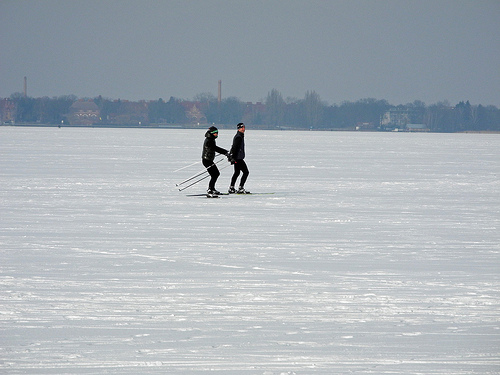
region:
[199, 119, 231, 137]
head of a person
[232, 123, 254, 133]
head of a person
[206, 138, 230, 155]
an arm of a person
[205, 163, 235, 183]
leg of a person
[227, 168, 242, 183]
leg of a person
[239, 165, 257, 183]
leg of a person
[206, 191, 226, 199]
feet of a person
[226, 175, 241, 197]
feet of a person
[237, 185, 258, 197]
feet of a person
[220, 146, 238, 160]
a hand of a person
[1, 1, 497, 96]
overcast sky on horizon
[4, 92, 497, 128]
hazy trees and buildings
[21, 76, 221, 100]
two smokestacks on horizon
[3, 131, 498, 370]
snow covered flat surface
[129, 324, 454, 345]
foot prints on snow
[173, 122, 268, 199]
two people on skis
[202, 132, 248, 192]
black clothing on bodies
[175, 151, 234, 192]
two sets of ski poles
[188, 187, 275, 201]
boots on top of skis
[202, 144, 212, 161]
light reflection on coat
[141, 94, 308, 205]
two people cross country skiing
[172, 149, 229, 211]
four ski poles on hands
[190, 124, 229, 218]
girl in back of man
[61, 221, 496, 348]
tracks in the snow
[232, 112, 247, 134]
black hat on man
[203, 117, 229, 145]
blue band and black hat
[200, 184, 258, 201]
feet on skis in snow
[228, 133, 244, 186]
man wearing dark clothing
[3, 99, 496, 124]
in the distance houses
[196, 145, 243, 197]
man holding girls hand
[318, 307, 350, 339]
white ice on ice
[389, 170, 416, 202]
white ice on ice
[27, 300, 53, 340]
white ice on ice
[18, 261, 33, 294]
white ice on ice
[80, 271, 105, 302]
white ice on ice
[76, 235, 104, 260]
white ice on ice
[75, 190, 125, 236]
white ice on ice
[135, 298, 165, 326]
white ice on ice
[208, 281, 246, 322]
white ice on ice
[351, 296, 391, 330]
white ice on ice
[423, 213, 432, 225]
part of a snow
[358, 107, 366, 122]
part of a building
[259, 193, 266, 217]
part of a board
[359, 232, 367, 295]
part of a snow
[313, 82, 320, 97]
part of a cloud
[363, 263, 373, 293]
edge of a snow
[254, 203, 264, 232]
part of a hill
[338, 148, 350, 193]
part of a floor